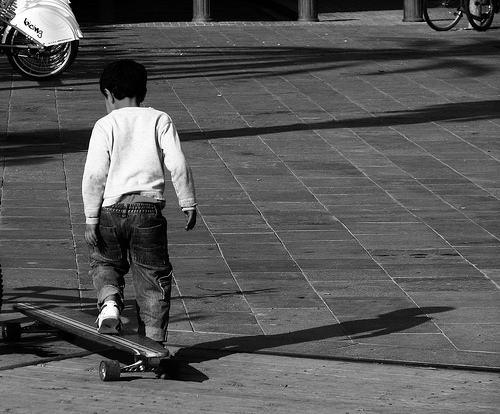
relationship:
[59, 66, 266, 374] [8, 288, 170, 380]
boy on a skateboard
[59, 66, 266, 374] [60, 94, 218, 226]
boy wearing sweater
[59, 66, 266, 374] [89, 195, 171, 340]
boy wearing jeans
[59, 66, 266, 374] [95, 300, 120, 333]
boy wearing shoe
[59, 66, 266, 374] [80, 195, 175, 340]
boy has jeans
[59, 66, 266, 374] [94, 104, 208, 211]
boy has sweater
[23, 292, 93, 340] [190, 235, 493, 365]
skateboard on ground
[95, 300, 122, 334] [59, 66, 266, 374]
shoe worn by boy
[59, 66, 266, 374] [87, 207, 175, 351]
boy wears jeans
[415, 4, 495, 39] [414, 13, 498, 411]
bicycle on right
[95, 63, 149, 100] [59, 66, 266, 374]
hair of boy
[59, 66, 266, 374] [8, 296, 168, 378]
boy has foot on skateboard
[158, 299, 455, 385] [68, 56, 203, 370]
shadow of young boy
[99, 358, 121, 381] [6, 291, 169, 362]
wheel on skateboard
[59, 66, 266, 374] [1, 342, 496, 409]
boy on walkway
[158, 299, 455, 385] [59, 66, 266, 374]
shadow of a boy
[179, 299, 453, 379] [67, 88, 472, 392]
shadow on ground